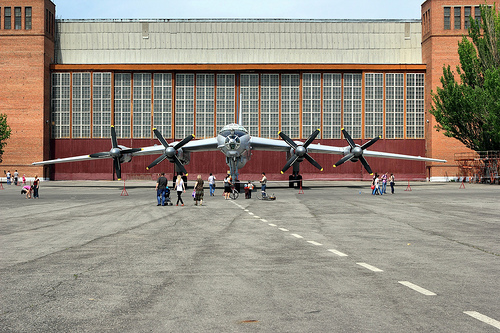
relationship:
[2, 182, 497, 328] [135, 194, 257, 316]
asphalt has lines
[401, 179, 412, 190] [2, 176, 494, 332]
safety triangle on ground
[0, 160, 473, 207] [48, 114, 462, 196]
people viewing plane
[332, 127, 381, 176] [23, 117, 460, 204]
prop of plane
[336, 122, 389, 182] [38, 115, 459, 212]
prop of a plane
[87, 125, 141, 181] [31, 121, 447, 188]
prop of a plane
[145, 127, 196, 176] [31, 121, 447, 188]
prop of a plane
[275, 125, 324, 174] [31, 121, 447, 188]
propeller of a plane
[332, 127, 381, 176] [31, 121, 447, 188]
prop of a plane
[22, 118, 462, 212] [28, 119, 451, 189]
jet on display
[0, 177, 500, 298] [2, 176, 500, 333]
dash on ground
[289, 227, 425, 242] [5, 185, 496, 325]
dash on road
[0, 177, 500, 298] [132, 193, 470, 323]
dash on road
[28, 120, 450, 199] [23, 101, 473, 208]
prop of plane